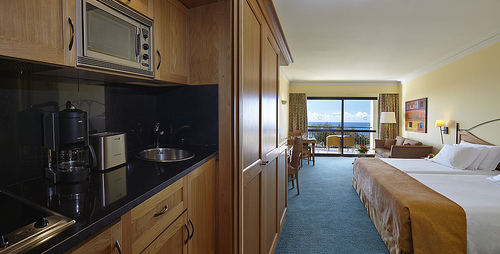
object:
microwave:
[78, 2, 157, 77]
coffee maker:
[58, 105, 87, 183]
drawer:
[124, 186, 188, 253]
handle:
[154, 205, 169, 217]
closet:
[236, 0, 280, 254]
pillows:
[429, 144, 481, 171]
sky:
[308, 100, 372, 121]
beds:
[353, 143, 500, 254]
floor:
[276, 152, 383, 252]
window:
[304, 98, 378, 154]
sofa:
[375, 136, 432, 159]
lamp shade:
[379, 112, 396, 124]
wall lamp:
[435, 119, 445, 144]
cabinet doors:
[0, 0, 190, 89]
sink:
[137, 147, 194, 162]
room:
[0, 0, 500, 253]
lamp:
[380, 111, 397, 139]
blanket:
[354, 155, 499, 253]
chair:
[287, 134, 301, 195]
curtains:
[289, 93, 309, 141]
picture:
[404, 98, 427, 134]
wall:
[276, 66, 500, 157]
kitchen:
[0, 0, 230, 254]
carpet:
[277, 154, 377, 253]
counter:
[1, 128, 220, 252]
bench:
[326, 134, 356, 152]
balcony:
[303, 126, 376, 157]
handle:
[156, 50, 161, 70]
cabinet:
[152, 0, 190, 86]